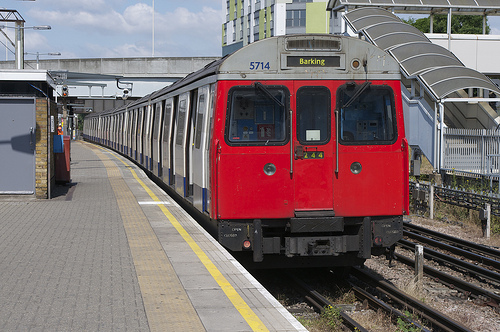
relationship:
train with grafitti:
[82, 32, 409, 273] [194, 77, 217, 198]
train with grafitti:
[82, 32, 409, 265] [166, 79, 216, 206]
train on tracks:
[82, 32, 409, 273] [266, 215, 498, 328]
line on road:
[77, 139, 271, 331] [0, 139, 309, 332]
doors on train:
[332, 87, 403, 214] [47, 65, 411, 224]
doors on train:
[215, 72, 304, 217] [47, 65, 411, 224]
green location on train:
[293, 51, 335, 73] [147, 17, 424, 278]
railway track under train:
[389, 250, 500, 307] [82, 32, 409, 273]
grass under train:
[331, 295, 361, 310] [82, 32, 409, 273]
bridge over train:
[65, 57, 195, 77] [224, 30, 414, 242]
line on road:
[77, 139, 271, 331] [8, 193, 240, 330]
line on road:
[149, 186, 184, 241] [76, 173, 177, 280]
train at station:
[82, 32, 409, 265] [0, 22, 275, 274]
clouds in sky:
[1, 1, 223, 55] [1, 0, 221, 57]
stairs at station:
[397, 77, 499, 179] [40, 52, 488, 300]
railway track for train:
[389, 250, 500, 307] [82, 32, 409, 273]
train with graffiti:
[82, 32, 409, 265] [248, 41, 442, 76]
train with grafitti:
[82, 32, 409, 273] [74, 30, 416, 270]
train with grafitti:
[82, 32, 409, 265] [78, 29, 431, 295]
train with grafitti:
[82, 32, 409, 273] [101, 30, 417, 263]